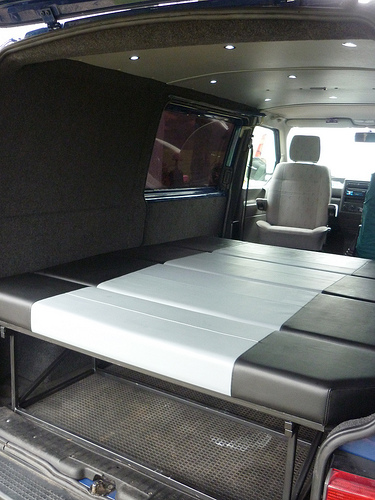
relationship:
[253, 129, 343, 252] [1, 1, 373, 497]
seat in vehicle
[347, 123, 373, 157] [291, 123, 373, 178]
mirror in window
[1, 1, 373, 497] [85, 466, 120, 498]
vehicle has latch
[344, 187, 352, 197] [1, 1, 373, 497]
light in vehicle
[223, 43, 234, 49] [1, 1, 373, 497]
light in vehicle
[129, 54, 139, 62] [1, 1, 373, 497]
light in vehicle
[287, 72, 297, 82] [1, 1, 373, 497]
light in vehicle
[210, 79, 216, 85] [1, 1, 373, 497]
light in vehicle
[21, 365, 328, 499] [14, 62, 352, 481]
bumps on interior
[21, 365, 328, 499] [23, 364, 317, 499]
bumps on interior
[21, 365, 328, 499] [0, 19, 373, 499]
bumps on black interior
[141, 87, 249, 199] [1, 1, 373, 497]
mirror in vehicle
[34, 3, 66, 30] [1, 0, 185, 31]
latch on trunk door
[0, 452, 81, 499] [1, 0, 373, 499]
bumper on interior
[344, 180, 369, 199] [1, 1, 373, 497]
radio in a vehicle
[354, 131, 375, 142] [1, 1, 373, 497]
mirror in vehicle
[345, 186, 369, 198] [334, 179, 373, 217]
radio in dash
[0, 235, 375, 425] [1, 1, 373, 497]
cushions in vehicle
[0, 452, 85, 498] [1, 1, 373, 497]
bumper in vehicle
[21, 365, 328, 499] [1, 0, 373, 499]
bumps on interior